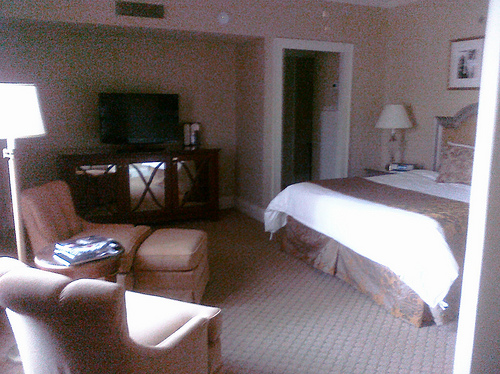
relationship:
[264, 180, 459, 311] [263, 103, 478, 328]
blanket at foot of bed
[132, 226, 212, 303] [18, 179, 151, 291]
ottoman matched to chair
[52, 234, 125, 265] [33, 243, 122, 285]
stack of magazines sitting on end table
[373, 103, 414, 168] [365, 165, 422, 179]
lamp sitting on table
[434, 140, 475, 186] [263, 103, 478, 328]
pillow laying on bed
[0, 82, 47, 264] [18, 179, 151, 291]
floor lamp next to chair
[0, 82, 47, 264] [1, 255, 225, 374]
floor lamp next to chair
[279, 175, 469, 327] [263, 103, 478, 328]
blanket on top of bed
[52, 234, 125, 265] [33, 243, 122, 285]
stack of magazines lying on end table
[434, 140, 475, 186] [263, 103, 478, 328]
pillow propped on bed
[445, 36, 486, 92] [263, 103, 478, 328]
picture above bed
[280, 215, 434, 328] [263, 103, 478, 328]
bed skirt hanging on bed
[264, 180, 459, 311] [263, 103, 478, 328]
blanket lying on bed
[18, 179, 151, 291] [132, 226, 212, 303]
chair next to ottoman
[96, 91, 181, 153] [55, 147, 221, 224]
television sitting on stand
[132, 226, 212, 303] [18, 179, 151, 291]
ottoman in front of chair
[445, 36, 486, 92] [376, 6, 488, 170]
picture hanging on wall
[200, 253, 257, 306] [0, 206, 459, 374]
shadow cast on floor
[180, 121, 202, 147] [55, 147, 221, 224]
books sitting on stand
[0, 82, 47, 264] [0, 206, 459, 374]
floor lamp standing on floor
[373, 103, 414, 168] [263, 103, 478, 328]
lamp next to bed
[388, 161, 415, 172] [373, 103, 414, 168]
book next to lamp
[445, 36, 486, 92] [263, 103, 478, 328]
picture hanging above bed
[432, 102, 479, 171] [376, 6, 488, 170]
headboard touching wall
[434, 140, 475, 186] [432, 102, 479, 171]
pillow leaning against headboard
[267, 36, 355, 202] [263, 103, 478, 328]
doorway to left of bed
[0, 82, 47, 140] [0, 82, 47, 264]
lamp shade part of floor lamp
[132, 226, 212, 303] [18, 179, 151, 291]
ottoman next to chair